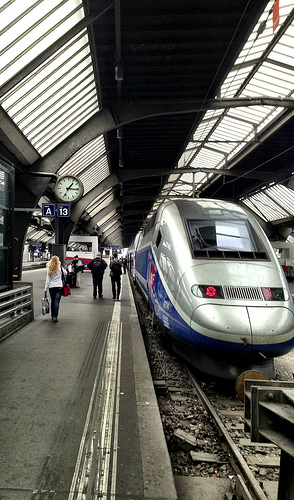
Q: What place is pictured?
A: It is a walkway.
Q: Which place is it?
A: It is a walkway.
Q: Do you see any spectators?
A: No, there are no spectators.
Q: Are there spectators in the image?
A: No, there are no spectators.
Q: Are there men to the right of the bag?
A: Yes, there is a man to the right of the bag.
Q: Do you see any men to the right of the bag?
A: Yes, there is a man to the right of the bag.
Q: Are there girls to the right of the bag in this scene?
A: No, there is a man to the right of the bag.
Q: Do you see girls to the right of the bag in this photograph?
A: No, there is a man to the right of the bag.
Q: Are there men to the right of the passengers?
A: Yes, there is a man to the right of the passengers.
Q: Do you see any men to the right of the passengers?
A: Yes, there is a man to the right of the passengers.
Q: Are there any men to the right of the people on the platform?
A: Yes, there is a man to the right of the passengers.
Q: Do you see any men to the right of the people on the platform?
A: Yes, there is a man to the right of the passengers.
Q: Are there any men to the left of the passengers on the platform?
A: No, the man is to the right of the passengers.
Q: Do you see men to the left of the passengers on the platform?
A: No, the man is to the right of the passengers.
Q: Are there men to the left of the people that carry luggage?
A: No, the man is to the right of the passengers.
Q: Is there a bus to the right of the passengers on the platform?
A: No, there is a man to the right of the passengers.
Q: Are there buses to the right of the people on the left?
A: No, there is a man to the right of the passengers.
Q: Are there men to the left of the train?
A: Yes, there is a man to the left of the train.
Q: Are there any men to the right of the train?
A: No, the man is to the left of the train.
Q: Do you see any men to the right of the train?
A: No, the man is to the left of the train.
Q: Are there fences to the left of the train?
A: No, there is a man to the left of the train.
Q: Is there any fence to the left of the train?
A: No, there is a man to the left of the train.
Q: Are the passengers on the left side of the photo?
A: Yes, the passengers are on the left of the image.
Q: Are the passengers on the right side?
A: No, the passengers are on the left of the image.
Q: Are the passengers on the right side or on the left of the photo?
A: The passengers are on the left of the image.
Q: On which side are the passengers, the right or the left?
A: The passengers are on the left of the image.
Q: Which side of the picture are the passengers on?
A: The passengers are on the left of the image.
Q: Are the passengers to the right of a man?
A: No, the passengers are to the left of a man.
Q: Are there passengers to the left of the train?
A: Yes, there are passengers to the left of the train.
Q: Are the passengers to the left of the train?
A: Yes, the passengers are to the left of the train.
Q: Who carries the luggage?
A: The passengers carry the luggage.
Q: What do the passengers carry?
A: The passengers carry luggage.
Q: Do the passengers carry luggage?
A: Yes, the passengers carry luggage.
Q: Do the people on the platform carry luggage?
A: Yes, the passengers carry luggage.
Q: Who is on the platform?
A: The passengers are on the platform.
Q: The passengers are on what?
A: The passengers are on the platform.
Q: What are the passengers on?
A: The passengers are on the platform.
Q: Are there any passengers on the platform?
A: Yes, there are passengers on the platform.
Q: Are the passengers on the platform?
A: Yes, the passengers are on the platform.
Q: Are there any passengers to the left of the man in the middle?
A: Yes, there are passengers to the left of the man.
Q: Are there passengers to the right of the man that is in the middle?
A: No, the passengers are to the left of the man.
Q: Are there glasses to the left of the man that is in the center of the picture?
A: No, there are passengers to the left of the man.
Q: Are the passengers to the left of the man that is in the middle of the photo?
A: Yes, the passengers are to the left of the man.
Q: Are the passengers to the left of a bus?
A: No, the passengers are to the left of the man.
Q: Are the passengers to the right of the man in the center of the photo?
A: No, the passengers are to the left of the man.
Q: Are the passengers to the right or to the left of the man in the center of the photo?
A: The passengers are to the left of the man.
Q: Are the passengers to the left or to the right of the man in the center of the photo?
A: The passengers are to the left of the man.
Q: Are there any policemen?
A: No, there are no policemen.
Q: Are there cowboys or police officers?
A: No, there are no police officers or cowboys.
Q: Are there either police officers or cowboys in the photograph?
A: No, there are no police officers or cowboys.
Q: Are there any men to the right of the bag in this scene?
A: Yes, there is a man to the right of the bag.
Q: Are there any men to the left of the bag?
A: No, the man is to the right of the bag.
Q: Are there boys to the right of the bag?
A: No, there is a man to the right of the bag.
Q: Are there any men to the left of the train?
A: Yes, there is a man to the left of the train.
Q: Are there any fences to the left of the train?
A: No, there is a man to the left of the train.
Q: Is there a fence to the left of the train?
A: No, there is a man to the left of the train.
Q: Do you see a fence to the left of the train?
A: No, there is a man to the left of the train.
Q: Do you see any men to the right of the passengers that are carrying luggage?
A: Yes, there is a man to the right of the passengers.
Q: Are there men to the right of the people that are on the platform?
A: Yes, there is a man to the right of the passengers.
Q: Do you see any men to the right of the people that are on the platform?
A: Yes, there is a man to the right of the passengers.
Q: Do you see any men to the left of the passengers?
A: No, the man is to the right of the passengers.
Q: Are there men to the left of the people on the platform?
A: No, the man is to the right of the passengers.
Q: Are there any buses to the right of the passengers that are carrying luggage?
A: No, there is a man to the right of the passengers.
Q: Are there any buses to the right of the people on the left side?
A: No, there is a man to the right of the passengers.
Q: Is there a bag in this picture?
A: Yes, there is a bag.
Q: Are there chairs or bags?
A: Yes, there is a bag.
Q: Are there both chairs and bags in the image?
A: No, there is a bag but no chairs.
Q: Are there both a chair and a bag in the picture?
A: No, there is a bag but no chairs.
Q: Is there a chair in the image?
A: No, there are no chairs.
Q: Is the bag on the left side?
A: Yes, the bag is on the left of the image.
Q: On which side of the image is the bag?
A: The bag is on the left of the image.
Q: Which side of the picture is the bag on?
A: The bag is on the left of the image.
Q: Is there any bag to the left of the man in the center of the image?
A: Yes, there is a bag to the left of the man.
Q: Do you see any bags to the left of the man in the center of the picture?
A: Yes, there is a bag to the left of the man.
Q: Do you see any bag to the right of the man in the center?
A: No, the bag is to the left of the man.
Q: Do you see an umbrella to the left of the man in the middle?
A: No, there is a bag to the left of the man.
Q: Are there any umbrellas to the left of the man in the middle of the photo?
A: No, there is a bag to the left of the man.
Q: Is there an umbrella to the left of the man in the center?
A: No, there is a bag to the left of the man.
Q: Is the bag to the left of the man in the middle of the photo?
A: Yes, the bag is to the left of the man.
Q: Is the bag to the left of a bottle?
A: No, the bag is to the left of the man.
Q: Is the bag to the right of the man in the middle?
A: No, the bag is to the left of the man.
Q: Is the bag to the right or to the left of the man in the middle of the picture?
A: The bag is to the left of the man.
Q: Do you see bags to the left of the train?
A: Yes, there is a bag to the left of the train.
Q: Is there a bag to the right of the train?
A: No, the bag is to the left of the train.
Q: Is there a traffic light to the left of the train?
A: No, there is a bag to the left of the train.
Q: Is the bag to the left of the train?
A: Yes, the bag is to the left of the train.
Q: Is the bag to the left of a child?
A: No, the bag is to the left of the train.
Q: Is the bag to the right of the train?
A: No, the bag is to the left of the train.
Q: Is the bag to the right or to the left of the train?
A: The bag is to the left of the train.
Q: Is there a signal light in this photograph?
A: No, there are no traffic lights.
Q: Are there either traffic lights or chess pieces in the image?
A: No, there are no traffic lights or chess pieces.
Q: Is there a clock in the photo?
A: Yes, there is a clock.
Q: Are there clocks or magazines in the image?
A: Yes, there is a clock.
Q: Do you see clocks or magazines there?
A: Yes, there is a clock.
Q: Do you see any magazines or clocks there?
A: Yes, there is a clock.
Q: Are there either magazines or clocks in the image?
A: Yes, there is a clock.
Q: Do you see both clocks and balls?
A: No, there is a clock but no balls.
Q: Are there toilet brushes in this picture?
A: No, there are no toilet brushes.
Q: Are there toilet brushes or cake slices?
A: No, there are no toilet brushes or cake slices.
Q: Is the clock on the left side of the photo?
A: Yes, the clock is on the left of the image.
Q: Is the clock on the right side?
A: No, the clock is on the left of the image.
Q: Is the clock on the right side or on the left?
A: The clock is on the left of the image.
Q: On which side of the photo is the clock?
A: The clock is on the left of the image.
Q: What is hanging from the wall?
A: The clock is hanging from the wall.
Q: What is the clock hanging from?
A: The clock is hanging from the wall.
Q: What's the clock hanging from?
A: The clock is hanging from the wall.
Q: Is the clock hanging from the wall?
A: Yes, the clock is hanging from the wall.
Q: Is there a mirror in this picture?
A: No, there are no mirrors.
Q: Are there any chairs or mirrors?
A: No, there are no mirrors or chairs.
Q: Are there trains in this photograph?
A: Yes, there is a train.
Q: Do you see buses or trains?
A: Yes, there is a train.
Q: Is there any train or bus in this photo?
A: Yes, there is a train.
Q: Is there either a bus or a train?
A: Yes, there is a train.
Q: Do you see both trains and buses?
A: No, there is a train but no buses.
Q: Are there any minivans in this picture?
A: No, there are no minivans.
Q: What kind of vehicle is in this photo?
A: The vehicle is a train.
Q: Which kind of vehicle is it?
A: The vehicle is a train.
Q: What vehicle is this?
A: This is a train.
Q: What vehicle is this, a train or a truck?
A: This is a train.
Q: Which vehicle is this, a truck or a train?
A: This is a train.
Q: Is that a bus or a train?
A: That is a train.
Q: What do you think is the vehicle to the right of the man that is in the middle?
A: The vehicle is a train.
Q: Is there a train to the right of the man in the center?
A: Yes, there is a train to the right of the man.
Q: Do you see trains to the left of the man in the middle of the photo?
A: No, the train is to the right of the man.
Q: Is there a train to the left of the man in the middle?
A: No, the train is to the right of the man.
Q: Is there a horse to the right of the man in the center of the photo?
A: No, there is a train to the right of the man.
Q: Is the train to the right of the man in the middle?
A: Yes, the train is to the right of the man.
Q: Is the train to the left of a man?
A: No, the train is to the right of a man.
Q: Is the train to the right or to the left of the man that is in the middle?
A: The train is to the right of the man.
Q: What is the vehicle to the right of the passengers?
A: The vehicle is a train.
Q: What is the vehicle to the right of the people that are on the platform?
A: The vehicle is a train.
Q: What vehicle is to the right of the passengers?
A: The vehicle is a train.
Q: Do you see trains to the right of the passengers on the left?
A: Yes, there is a train to the right of the passengers.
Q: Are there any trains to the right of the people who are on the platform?
A: Yes, there is a train to the right of the passengers.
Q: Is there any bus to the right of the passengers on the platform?
A: No, there is a train to the right of the passengers.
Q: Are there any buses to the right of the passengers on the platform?
A: No, there is a train to the right of the passengers.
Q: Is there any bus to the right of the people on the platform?
A: No, there is a train to the right of the passengers.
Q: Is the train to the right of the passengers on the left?
A: Yes, the train is to the right of the passengers.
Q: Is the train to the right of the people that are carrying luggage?
A: Yes, the train is to the right of the passengers.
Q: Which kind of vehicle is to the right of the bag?
A: The vehicle is a train.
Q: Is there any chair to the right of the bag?
A: No, there is a train to the right of the bag.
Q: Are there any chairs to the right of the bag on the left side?
A: No, there is a train to the right of the bag.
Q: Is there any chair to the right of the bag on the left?
A: No, there is a train to the right of the bag.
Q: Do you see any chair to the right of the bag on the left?
A: No, there is a train to the right of the bag.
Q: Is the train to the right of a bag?
A: Yes, the train is to the right of a bag.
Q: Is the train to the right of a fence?
A: No, the train is to the right of a bag.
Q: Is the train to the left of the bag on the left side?
A: No, the train is to the right of the bag.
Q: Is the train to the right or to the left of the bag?
A: The train is to the right of the bag.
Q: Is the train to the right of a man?
A: Yes, the train is to the right of a man.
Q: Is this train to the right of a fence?
A: No, the train is to the right of a man.